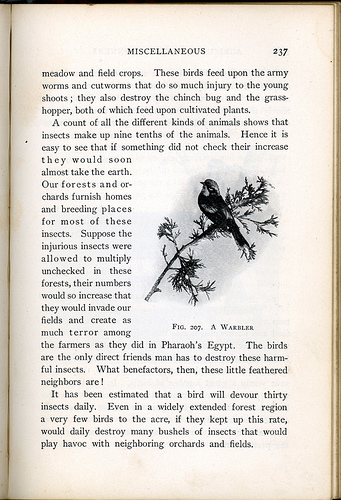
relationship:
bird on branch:
[196, 175, 246, 250] [143, 171, 278, 305]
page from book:
[9, 3, 336, 497] [2, 2, 337, 495]